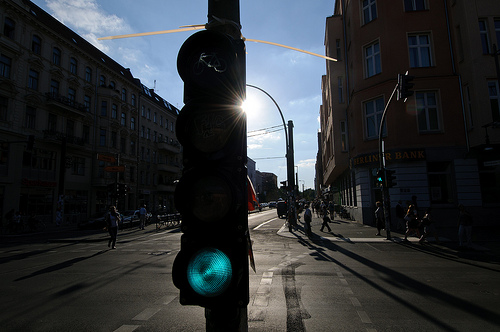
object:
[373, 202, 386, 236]
people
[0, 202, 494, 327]
road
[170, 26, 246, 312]
light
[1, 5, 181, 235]
building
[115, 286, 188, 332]
dash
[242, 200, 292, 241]
dash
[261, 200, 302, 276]
dash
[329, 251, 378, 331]
dash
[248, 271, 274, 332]
dash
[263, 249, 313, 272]
dash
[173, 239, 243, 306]
traffic light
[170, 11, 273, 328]
pole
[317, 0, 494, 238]
building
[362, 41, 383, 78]
window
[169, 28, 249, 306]
traffic light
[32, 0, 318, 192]
sky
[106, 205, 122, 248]
person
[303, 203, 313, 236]
person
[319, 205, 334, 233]
person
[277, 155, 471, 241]
sidewalk